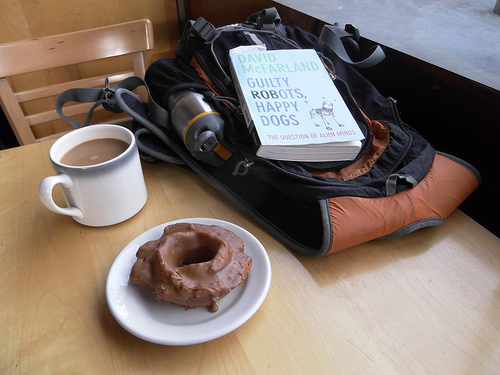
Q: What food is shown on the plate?
A: A donut.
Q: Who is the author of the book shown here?
A: David McFarland.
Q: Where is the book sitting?
A: On a backpack.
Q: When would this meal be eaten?
A: In the morning for breakfast.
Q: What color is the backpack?
A: Orange.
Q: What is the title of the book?
A: Guilty Robots, Happy Dogs.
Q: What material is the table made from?
A: Wood.